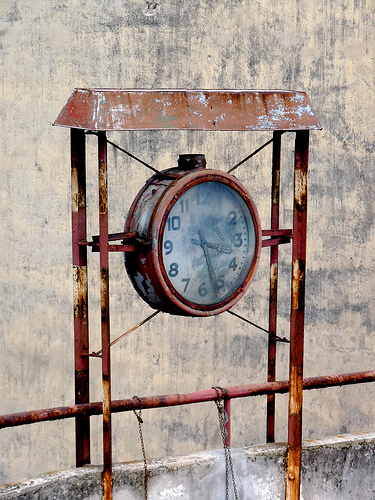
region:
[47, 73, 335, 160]
top of metal casing hold clock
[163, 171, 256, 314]
dirty face of clock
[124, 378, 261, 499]
chains attached to metal bar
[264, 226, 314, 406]
two rusted metal bars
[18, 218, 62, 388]
dirty cement wall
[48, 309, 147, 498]
rusted metal poles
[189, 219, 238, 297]
two hands on front of clock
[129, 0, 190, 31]
chip missing from cement wall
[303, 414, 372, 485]
edge of cement wall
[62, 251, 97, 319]
two tone paint on rusty bar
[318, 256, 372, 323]
gray stains on the wall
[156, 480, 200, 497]
white paint on the well wall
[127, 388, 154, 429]
black chain attached to red pole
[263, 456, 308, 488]
large gold screw on post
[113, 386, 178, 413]
black soot on red post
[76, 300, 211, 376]
pole attached to clock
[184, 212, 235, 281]
dirt on the front of clock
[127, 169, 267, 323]
red face on edge of clock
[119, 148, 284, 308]
large red chipped clock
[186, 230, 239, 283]
hands on the face of the clock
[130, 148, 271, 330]
fogged over clock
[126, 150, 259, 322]
old clock reading 3:27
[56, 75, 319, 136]
tin roof with white spots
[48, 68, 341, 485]
tin stand for a clock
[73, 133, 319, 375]
clock strung between posts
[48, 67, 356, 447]
clock strung between tin rods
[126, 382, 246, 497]
wire hanging off a metal rod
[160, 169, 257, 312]
clock face with arabic numbers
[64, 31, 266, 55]
scratched up concrete wall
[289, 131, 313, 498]
old and rusted metal rod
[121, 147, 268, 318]
dirty and old clock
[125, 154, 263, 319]
old clock hanging on post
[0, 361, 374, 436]
rusty and red railing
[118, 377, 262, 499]
thin and rusty chains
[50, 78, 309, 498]
red and rusty clock post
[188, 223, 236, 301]
grey clock hands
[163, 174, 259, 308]
cloudy glass on clock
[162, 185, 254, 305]
black numbers on clock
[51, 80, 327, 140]
rusty roof over on top of clock post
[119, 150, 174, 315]
peeling paint on clock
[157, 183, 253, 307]
clock with dirty white face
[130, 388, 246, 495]
chains hanging from pole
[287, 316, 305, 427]
red rusted vertical pole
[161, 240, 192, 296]
black numbers on clock face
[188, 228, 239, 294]
two hands on clock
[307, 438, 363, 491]
discolored cement wall edge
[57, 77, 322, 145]
rusted cover over clock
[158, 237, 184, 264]
number nine on clock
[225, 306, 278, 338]
rod underneath clock frame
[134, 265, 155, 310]
exposed metal on clock frame